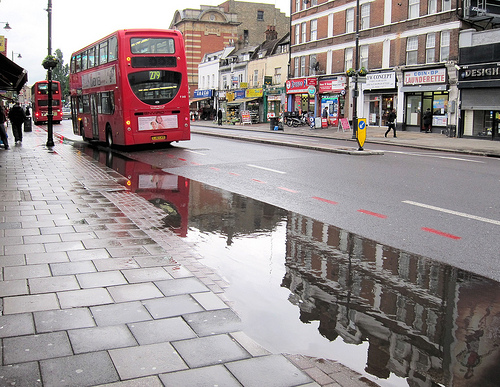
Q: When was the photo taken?
A: Daytime.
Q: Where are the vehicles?
A: Street.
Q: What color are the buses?
A: Red.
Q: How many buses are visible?
A: Two.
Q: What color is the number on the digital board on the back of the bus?
A: Green.